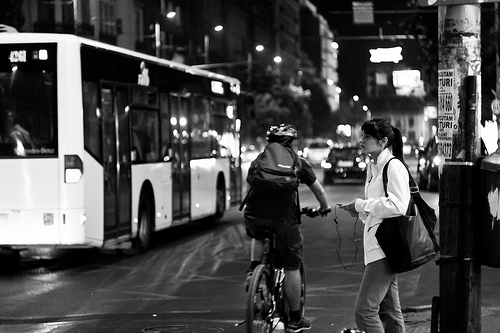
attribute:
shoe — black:
[283, 316, 313, 331]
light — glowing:
[207, 22, 226, 32]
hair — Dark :
[342, 107, 439, 167]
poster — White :
[438, 66, 460, 159]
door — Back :
[92, 79, 130, 236]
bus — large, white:
[1, 24, 242, 254]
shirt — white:
[352, 145, 412, 267]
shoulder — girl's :
[372, 157, 418, 236]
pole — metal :
[438, 3, 481, 323]